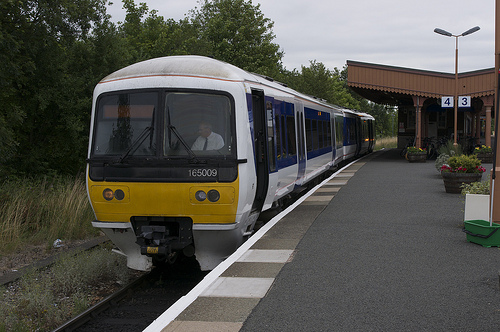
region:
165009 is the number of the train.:
[182, 163, 221, 182]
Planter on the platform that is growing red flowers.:
[433, 147, 485, 192]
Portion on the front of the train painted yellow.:
[81, 170, 243, 230]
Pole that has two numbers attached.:
[440, 87, 478, 114]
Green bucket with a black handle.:
[460, 211, 497, 255]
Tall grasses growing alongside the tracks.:
[2, 169, 87, 251]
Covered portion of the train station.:
[341, 45, 496, 158]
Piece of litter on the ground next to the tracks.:
[46, 234, 66, 251]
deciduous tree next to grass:
[1, 0, 84, 187]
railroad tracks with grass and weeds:
[1, 176, 84, 330]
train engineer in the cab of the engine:
[189, 120, 226, 155]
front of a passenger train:
[84, 54, 245, 276]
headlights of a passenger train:
[88, 182, 237, 206]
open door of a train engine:
[246, 83, 268, 228]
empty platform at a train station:
[167, 161, 437, 330]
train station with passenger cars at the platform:
[344, 57, 498, 161]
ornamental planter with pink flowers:
[436, 151, 488, 194]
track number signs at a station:
[439, 94, 472, 108]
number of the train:
[189, 163, 221, 179]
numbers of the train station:
[441, 93, 482, 115]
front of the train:
[71, 47, 283, 263]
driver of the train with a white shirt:
[192, 117, 227, 154]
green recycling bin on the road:
[462, 209, 497, 247]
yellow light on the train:
[144, 242, 164, 257]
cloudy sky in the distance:
[307, 12, 413, 54]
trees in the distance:
[4, 6, 261, 58]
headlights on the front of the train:
[99, 182, 227, 209]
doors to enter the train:
[289, 98, 314, 180]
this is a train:
[48, 19, 498, 299]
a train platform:
[318, 44, 498, 181]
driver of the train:
[168, 100, 245, 165]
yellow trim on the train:
[65, 142, 245, 244]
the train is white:
[72, 39, 285, 259]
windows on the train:
[226, 85, 386, 170]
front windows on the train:
[78, 73, 245, 183]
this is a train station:
[325, 14, 499, 194]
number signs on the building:
[425, 73, 486, 130]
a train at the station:
[85, 55, 377, 272]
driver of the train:
[190, 123, 224, 151]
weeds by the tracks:
[1, 170, 129, 330]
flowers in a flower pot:
[440, 153, 483, 191]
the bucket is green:
[464, 215, 499, 245]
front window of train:
[91, 90, 236, 180]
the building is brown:
[345, 59, 498, 153]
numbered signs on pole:
[440, 94, 470, 107]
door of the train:
[250, 86, 270, 212]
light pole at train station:
[432, 25, 479, 147]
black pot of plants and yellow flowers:
[403, 144, 428, 163]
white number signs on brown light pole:
[440, 92, 473, 109]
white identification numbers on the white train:
[185, 163, 221, 178]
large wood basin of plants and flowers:
[437, 152, 484, 192]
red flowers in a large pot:
[439, 162, 466, 194]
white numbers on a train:
[187, 165, 217, 177]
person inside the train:
[190, 119, 223, 150]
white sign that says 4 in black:
[441, 94, 453, 107]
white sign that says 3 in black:
[458, 95, 470, 107]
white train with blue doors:
[84, 54, 376, 269]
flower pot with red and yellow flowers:
[406, 144, 426, 161]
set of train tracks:
[53, 267, 200, 329]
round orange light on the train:
[103, 187, 113, 199]